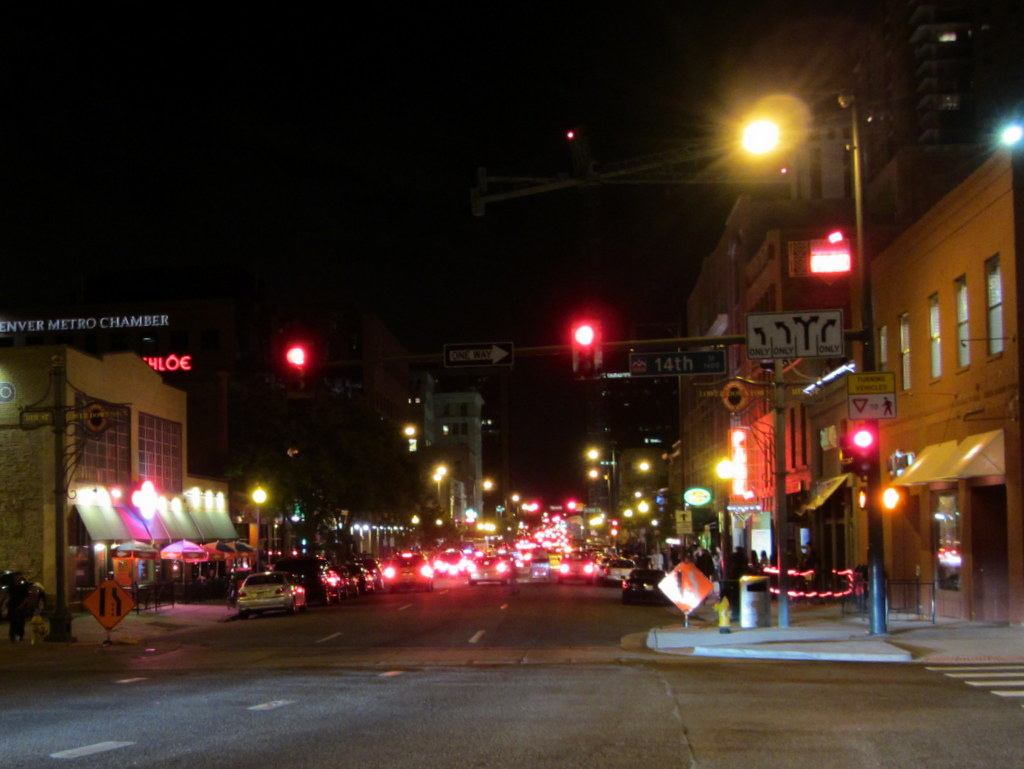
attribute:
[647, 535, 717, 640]
sign — orange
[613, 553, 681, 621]
car — black